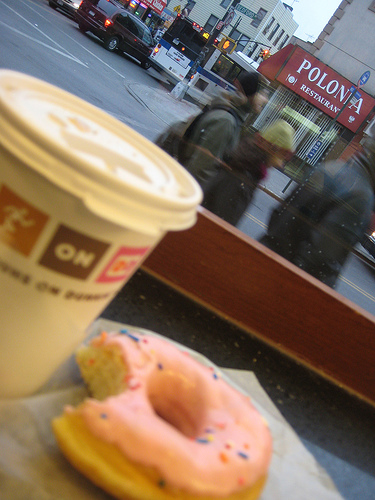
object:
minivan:
[79, 0, 153, 67]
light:
[264, 49, 269, 54]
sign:
[212, 32, 237, 54]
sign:
[224, 11, 234, 27]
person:
[150, 72, 271, 207]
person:
[202, 117, 294, 227]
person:
[256, 117, 373, 286]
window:
[211, 53, 234, 77]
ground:
[0, 29, 99, 131]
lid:
[0, 68, 202, 233]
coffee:
[51, 328, 271, 498]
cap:
[251, 118, 295, 163]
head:
[258, 113, 296, 158]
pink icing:
[130, 382, 141, 391]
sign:
[279, 45, 373, 131]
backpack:
[154, 105, 224, 162]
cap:
[235, 68, 264, 98]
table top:
[17, 360, 372, 493]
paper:
[8, 365, 345, 500]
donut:
[54, 328, 273, 499]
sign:
[358, 70, 371, 87]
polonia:
[295, 59, 363, 115]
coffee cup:
[0, 67, 204, 399]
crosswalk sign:
[218, 36, 237, 54]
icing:
[88, 325, 272, 493]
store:
[256, 39, 373, 176]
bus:
[148, 14, 261, 107]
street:
[2, 1, 373, 313]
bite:
[52, 332, 134, 424]